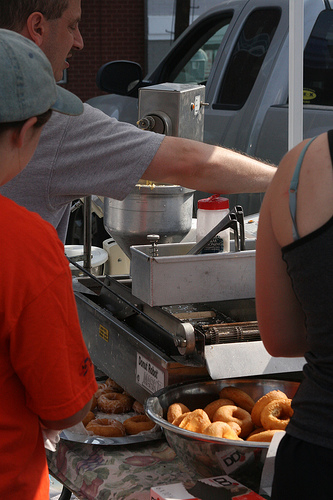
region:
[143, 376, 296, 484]
a metal bowl on the table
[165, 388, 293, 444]
brown donuts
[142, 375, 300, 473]
a metal bowl full of donuts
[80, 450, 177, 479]
a white table cloth on the table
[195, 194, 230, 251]
a clear bottle with a red top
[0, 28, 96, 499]
a person wearing a red shirt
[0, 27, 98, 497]
a person wearing a blue cap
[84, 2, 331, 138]
a silver truck parked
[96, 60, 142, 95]
a mirror off of the truck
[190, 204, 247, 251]
silver tongs on the side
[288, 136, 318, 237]
light blue bra strap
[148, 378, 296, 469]
metal bowl full of donuts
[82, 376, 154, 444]
plate with donuts on it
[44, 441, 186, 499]
floral pattern on the table cloth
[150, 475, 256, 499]
box of plastic gloves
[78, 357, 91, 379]
black logo on the red shirt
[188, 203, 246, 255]
two handles for metal spatulas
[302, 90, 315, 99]
yellow oval sticker on the window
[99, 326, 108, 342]
yellow label on the donut machine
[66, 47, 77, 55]
brown mustache on the man's face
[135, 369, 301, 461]
freshly fried golden doughnuts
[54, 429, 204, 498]
vinyl fruit table cloth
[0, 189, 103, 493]
bright red tee shirt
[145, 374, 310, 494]
large shiny silver bowl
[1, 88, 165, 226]
grey jersey tee shirt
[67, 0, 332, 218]
parked shiny silver truck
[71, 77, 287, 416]
large doughnut frying machine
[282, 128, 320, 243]
light blue bra strap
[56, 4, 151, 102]
red brick building with grey cement grouting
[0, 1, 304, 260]
man making fried dough nuts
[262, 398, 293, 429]
a large doughnut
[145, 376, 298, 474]
part of a large gray bowl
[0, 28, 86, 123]
part of a baseball cap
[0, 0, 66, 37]
part of a man's short cut hair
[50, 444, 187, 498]
a colorful tablecloth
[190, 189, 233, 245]
part of a red and white bottle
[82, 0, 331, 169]
part of a white truck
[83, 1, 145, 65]
part of a brick building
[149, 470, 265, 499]
part of a trashcan box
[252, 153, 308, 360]
part of a woman's arm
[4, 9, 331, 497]
people are in a kitchen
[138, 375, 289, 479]
a bowl with donuts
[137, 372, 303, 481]
brown donuts are cooked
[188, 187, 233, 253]
a white bottle with red lid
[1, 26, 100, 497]
boy wears shirt color orange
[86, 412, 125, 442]
a cooked donut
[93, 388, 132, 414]
a cooked donut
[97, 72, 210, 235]
a mixer behind an arm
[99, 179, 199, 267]
a bowl of silver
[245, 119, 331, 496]
woman with a black dress